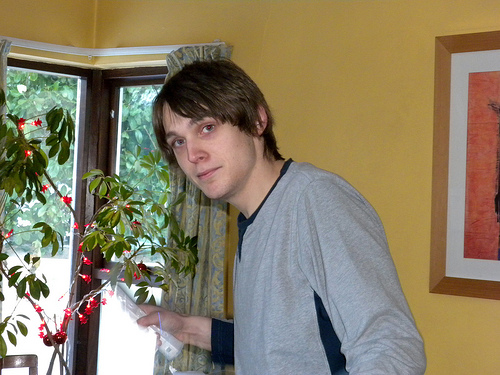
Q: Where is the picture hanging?
A: On the wall.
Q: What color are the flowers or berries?
A: Red.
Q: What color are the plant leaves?
A: Green.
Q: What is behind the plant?
A: Window.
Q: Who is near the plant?
A: A man.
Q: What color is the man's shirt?
A: Grey.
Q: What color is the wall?
A: Yellow.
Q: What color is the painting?
A: Red.